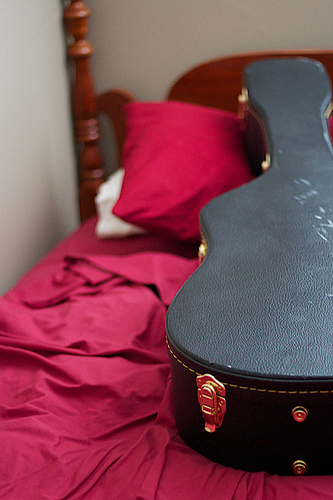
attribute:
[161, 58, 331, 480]
guitar case — black, large, leather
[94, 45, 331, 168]
head board — wooden, brown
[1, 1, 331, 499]
bed — made up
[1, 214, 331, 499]
sheets — red, fitted, maroon colored, wrinkled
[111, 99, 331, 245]
pillow — red, fluffy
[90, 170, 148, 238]
pillow — white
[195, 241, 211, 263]
latch — gold, small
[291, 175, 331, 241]
scruffs — white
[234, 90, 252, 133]
piece — metal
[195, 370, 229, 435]
grommets — metal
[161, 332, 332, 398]
stitching — yellow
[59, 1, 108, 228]
bed post — wooden, tall